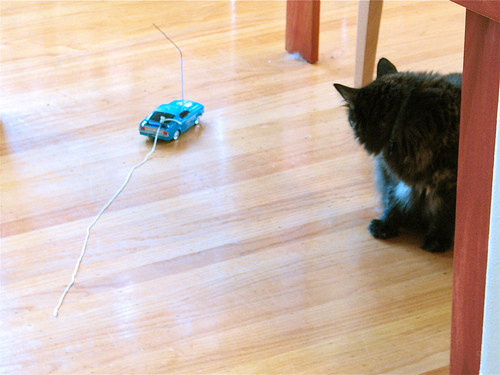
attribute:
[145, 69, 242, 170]
toy — small, blue, car, ar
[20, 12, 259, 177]
floor — wooden, wood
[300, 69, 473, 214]
cat — sitting, black, big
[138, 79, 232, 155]
car — remote, string, blue, white, rope, toy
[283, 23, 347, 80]
leg — bottom, table, dust, chair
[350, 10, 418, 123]
leg — chair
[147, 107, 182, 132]
window — black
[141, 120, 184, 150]
lights — red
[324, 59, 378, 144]
ear — small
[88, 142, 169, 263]
string — white